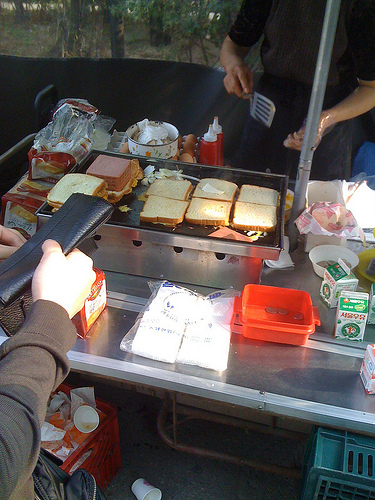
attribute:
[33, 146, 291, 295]
grill — rectangular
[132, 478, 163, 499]
cup — disposible, empty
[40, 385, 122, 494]
crate — small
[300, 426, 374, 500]
crate — plastic, green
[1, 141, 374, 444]
table — sturdy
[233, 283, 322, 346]
box — orange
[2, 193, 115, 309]
wallet — leather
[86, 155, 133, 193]
meat — pink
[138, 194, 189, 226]
bread — delicious, toasted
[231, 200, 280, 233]
bread — toasted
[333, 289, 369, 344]
carton — small, white, green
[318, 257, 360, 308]
carton — green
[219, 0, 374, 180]
person — cooking